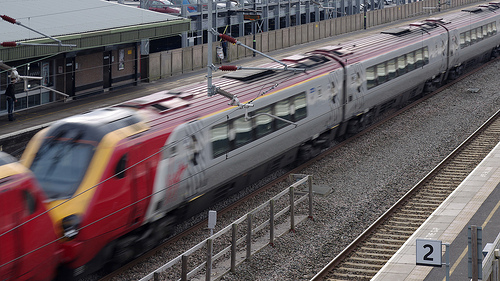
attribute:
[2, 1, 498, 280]
train — red, silver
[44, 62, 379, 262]
train — red, silver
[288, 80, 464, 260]
rocks — small